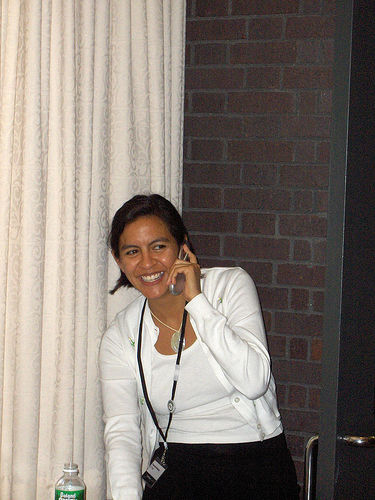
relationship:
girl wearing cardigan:
[99, 196, 301, 499] [100, 267, 283, 499]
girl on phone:
[99, 196, 301, 499] [168, 233, 190, 295]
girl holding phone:
[99, 196, 301, 499] [168, 233, 190, 295]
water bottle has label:
[55, 463, 87, 499] [55, 490, 88, 498]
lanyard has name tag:
[138, 300, 189, 488] [143, 459, 165, 488]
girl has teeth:
[99, 196, 301, 499] [140, 272, 163, 283]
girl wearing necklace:
[99, 196, 301, 499] [148, 309, 185, 350]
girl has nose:
[99, 196, 301, 499] [139, 245, 157, 270]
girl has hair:
[99, 196, 301, 499] [110, 196, 198, 296]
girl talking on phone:
[99, 196, 301, 499] [168, 233, 190, 295]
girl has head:
[99, 196, 301, 499] [111, 197, 190, 300]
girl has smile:
[99, 196, 301, 499] [135, 272, 165, 286]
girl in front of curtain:
[99, 196, 301, 499] [1, 1, 186, 499]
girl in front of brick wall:
[99, 196, 301, 499] [186, 2, 334, 499]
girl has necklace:
[99, 196, 301, 499] [148, 309, 185, 350]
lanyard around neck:
[138, 300, 189, 488] [147, 290, 192, 317]